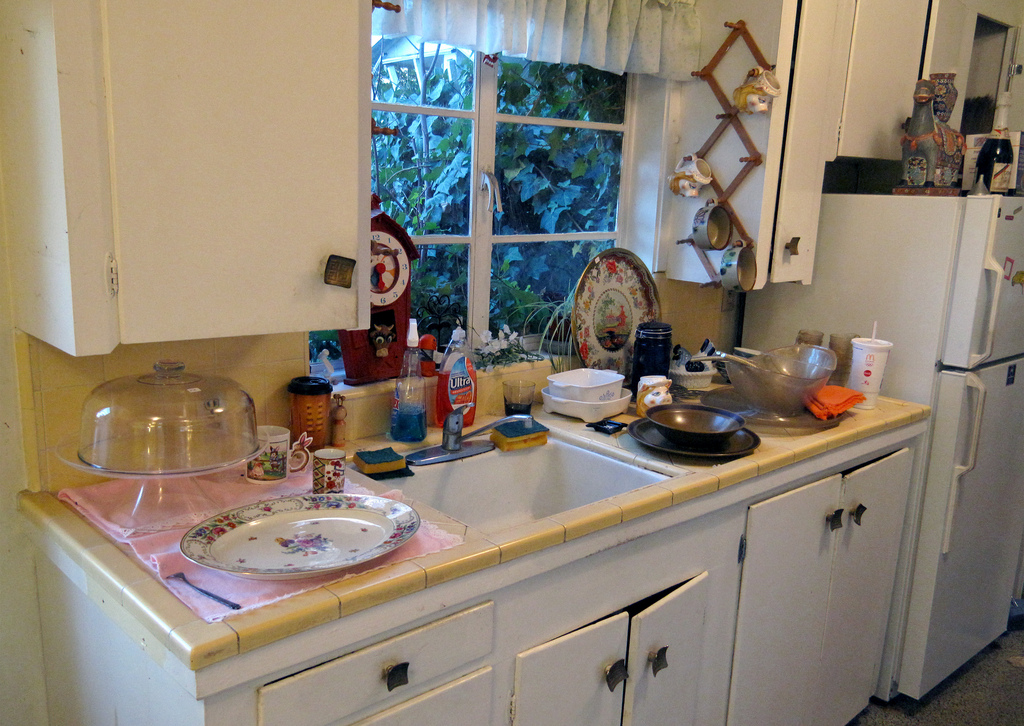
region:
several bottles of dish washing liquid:
[391, 313, 487, 453]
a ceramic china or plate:
[151, 474, 437, 585]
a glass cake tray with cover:
[49, 351, 278, 545]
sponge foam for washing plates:
[348, 435, 419, 489]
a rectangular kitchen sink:
[362, 398, 702, 560]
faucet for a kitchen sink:
[407, 402, 538, 479]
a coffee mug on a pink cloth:
[230, 416, 319, 497]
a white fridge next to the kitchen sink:
[803, 160, 1020, 701]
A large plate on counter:
[175, 490, 414, 586]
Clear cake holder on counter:
[49, 353, 264, 525]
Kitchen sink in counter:
[358, 405, 672, 542]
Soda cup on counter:
[845, 319, 888, 412]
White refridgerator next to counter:
[746, 174, 1018, 722]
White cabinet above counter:
[21, 1, 369, 362]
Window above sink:
[298, 0, 673, 402]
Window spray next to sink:
[386, 312, 437, 443]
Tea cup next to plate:
[305, 449, 357, 494]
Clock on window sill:
[340, 205, 430, 395]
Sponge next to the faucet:
[352, 440, 410, 475]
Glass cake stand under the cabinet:
[65, 357, 266, 522]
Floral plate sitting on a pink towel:
[175, 492, 420, 590]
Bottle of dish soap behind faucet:
[428, 325, 477, 428]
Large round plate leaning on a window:
[567, 241, 663, 382]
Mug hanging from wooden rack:
[661, 145, 710, 206]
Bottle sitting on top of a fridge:
[964, 83, 1013, 189]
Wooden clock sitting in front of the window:
[352, 189, 422, 383]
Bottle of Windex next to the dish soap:
[390, 313, 426, 447]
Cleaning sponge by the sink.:
[345, 437, 413, 480]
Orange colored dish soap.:
[430, 318, 487, 432]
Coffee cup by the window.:
[274, 362, 341, 464]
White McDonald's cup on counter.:
[841, 311, 899, 416]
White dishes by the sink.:
[533, 365, 633, 427]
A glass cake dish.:
[53, 356, 270, 528]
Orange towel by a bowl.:
[799, 372, 869, 424]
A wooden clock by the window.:
[329, 191, 434, 388]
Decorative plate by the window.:
[552, 239, 682, 394]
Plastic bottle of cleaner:
[391, 314, 431, 450]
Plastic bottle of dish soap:
[434, 321, 483, 435]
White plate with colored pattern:
[176, 489, 423, 579]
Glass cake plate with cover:
[61, 358, 265, 540]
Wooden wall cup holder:
[672, 14, 783, 302]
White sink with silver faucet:
[350, 404, 680, 550]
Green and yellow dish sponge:
[350, 444, 409, 479]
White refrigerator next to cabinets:
[738, 188, 1023, 701]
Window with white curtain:
[369, 2, 674, 386]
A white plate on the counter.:
[185, 496, 430, 579]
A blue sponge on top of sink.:
[360, 427, 409, 484]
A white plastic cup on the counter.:
[838, 312, 906, 411]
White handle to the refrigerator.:
[955, 372, 990, 487]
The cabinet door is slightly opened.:
[547, 572, 722, 645]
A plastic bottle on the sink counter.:
[370, 297, 432, 447]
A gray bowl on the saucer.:
[642, 401, 760, 456]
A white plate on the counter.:
[189, 494, 453, 589]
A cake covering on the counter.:
[68, 367, 290, 527]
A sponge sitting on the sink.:
[495, 417, 562, 455]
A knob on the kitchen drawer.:
[373, 641, 430, 706]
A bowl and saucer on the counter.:
[645, 398, 763, 476]